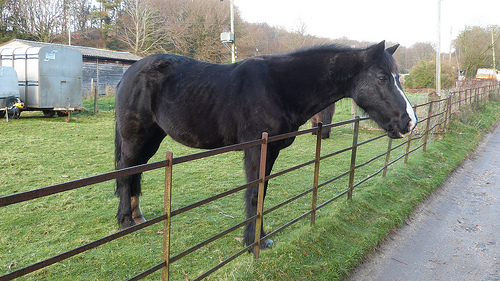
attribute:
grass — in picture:
[42, 123, 146, 224]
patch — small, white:
[389, 72, 424, 134]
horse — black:
[87, 28, 427, 240]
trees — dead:
[122, 10, 282, 59]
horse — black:
[114, 17, 443, 217]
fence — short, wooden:
[2, 80, 496, 277]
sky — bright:
[0, 2, 498, 55]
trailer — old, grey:
[3, 42, 85, 117]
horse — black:
[106, 29, 450, 229]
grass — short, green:
[4, 100, 441, 277]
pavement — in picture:
[434, 187, 496, 277]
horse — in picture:
[109, 43, 429, 279]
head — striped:
[318, 19, 460, 174]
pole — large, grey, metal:
[230, 0, 237, 64]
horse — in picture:
[108, 25, 465, 237]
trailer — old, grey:
[12, 26, 94, 126]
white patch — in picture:
[395, 80, 417, 125]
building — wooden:
[56, 36, 141, 128]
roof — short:
[74, 44, 143, 63]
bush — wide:
[400, 56, 457, 91]